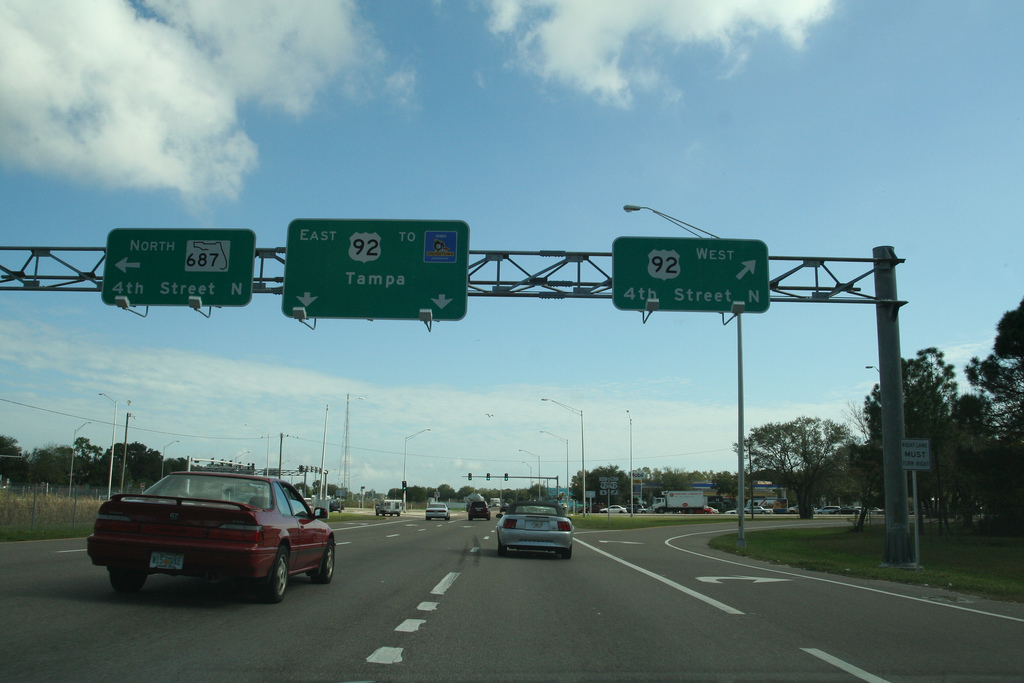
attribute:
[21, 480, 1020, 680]
multilanehighway — multi lane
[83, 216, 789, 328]
signs — large, green, white, street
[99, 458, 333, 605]
car — red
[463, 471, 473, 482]
light — traffic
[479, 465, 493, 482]
light — traffic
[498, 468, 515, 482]
light — traffic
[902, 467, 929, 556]
pole — black, white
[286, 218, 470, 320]
sign — middle